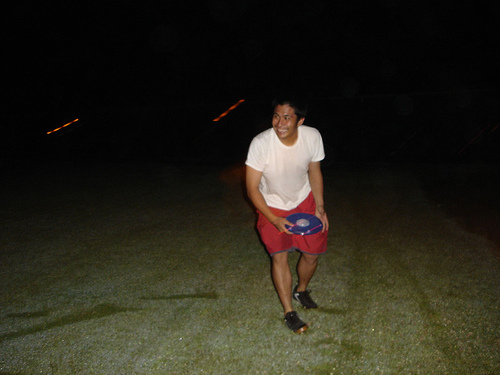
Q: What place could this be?
A: It is a field.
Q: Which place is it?
A: It is a field.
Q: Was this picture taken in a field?
A: Yes, it was taken in a field.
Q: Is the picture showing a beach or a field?
A: It is showing a field.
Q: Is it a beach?
A: No, it is a field.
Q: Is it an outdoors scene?
A: Yes, it is outdoors.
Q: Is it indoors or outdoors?
A: It is outdoors.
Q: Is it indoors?
A: No, it is outdoors.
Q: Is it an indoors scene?
A: No, it is outdoors.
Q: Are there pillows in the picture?
A: No, there are no pillows.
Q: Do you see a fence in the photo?
A: No, there are no fences.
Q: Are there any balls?
A: No, there are no balls.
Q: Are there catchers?
A: No, there are no catchers.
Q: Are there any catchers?
A: No, there are no catchers.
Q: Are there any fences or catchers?
A: No, there are no catchers or fences.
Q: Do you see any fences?
A: No, there are no fences.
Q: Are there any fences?
A: No, there are no fences.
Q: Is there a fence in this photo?
A: No, there are no fences.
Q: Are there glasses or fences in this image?
A: No, there are no fences or glasses.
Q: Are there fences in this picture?
A: No, there are no fences.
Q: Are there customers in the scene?
A: No, there are no customers.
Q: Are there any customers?
A: No, there are no customers.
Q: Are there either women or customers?
A: No, there are no customers or women.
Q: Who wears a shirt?
A: The guy wears a shirt.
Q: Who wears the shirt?
A: The guy wears a shirt.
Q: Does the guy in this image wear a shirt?
A: Yes, the guy wears a shirt.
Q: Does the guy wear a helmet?
A: No, the guy wears a shirt.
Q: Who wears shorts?
A: The guy wears shorts.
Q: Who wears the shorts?
A: The guy wears shorts.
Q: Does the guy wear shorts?
A: Yes, the guy wears shorts.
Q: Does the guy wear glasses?
A: No, the guy wears shorts.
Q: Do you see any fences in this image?
A: No, there are no fences.